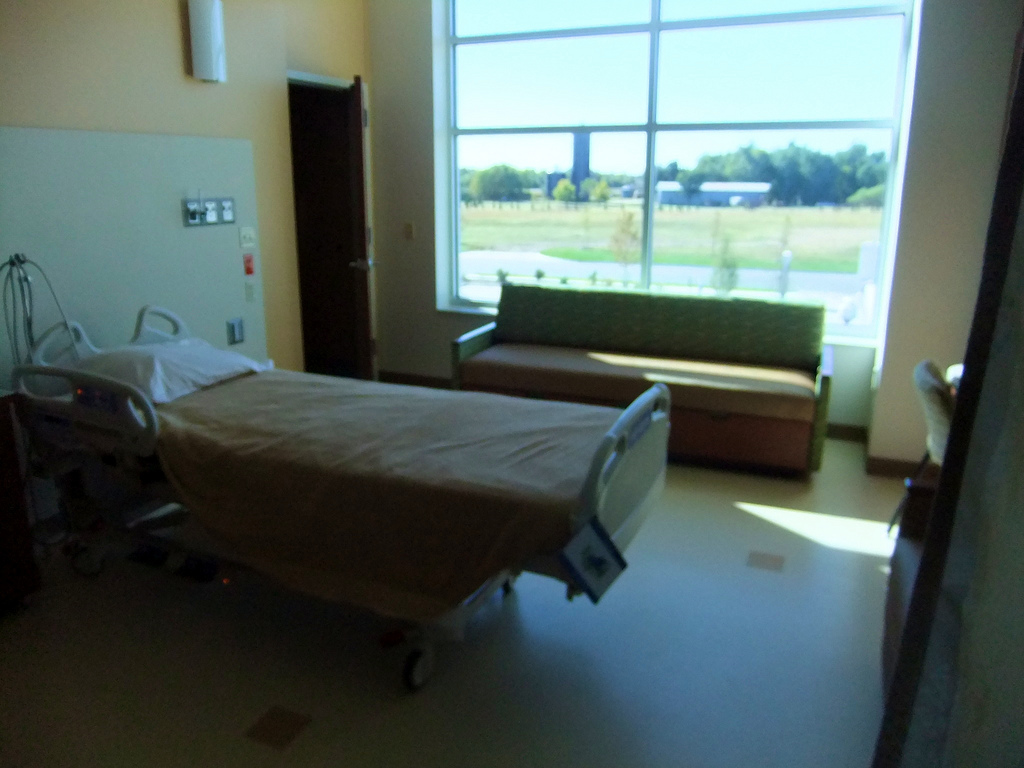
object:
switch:
[243, 253, 256, 275]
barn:
[654, 180, 772, 207]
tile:
[747, 549, 786, 571]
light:
[180, 0, 227, 84]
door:
[285, 72, 380, 382]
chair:
[889, 360, 976, 535]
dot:
[221, 577, 232, 584]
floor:
[0, 438, 925, 768]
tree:
[469, 164, 523, 210]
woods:
[452, 141, 892, 212]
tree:
[458, 170, 485, 208]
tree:
[551, 178, 575, 211]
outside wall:
[370, 0, 435, 382]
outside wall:
[863, 0, 1024, 475]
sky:
[451, 0, 924, 173]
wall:
[0, 0, 380, 401]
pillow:
[76, 334, 263, 407]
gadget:
[0, 253, 50, 286]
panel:
[432, 0, 912, 350]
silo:
[570, 132, 590, 198]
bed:
[11, 311, 673, 687]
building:
[0, 0, 1024, 768]